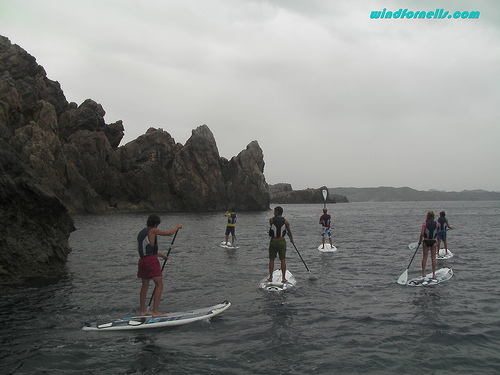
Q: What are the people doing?
A: Surfing in the water.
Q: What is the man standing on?
A: A surfboard.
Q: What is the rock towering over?
A: The water.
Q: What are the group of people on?
A: Paddle boards.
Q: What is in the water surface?
A: Ripples.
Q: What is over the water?
A: Rocky terrain.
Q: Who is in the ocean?
A: Six paddleboarders.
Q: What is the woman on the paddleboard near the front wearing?
A: Pink shorts.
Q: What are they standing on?
A: Boards.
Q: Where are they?
A: In the water.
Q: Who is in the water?
A: Men and women.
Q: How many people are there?
A: Six.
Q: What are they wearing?
A: Life jackets.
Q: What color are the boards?
A: White.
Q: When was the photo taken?
A: Daytime.